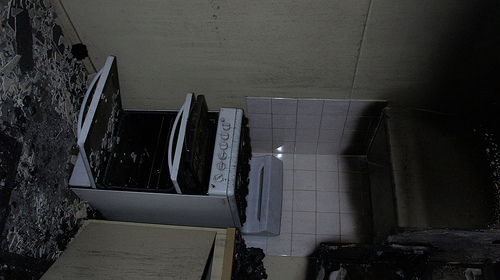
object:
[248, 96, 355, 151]
tile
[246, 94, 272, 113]
wall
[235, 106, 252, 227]
top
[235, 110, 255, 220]
eyes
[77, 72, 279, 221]
oven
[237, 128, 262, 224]
black burners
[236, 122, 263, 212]
burners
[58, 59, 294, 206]
stove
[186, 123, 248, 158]
knob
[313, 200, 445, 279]
cabinet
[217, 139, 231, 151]
white knob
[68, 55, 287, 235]
white stove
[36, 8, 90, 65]
tiles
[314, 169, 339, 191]
tile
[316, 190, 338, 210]
tile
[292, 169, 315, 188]
tile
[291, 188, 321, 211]
tile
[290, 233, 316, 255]
tile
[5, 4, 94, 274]
floor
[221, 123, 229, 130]
dial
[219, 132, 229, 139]
dial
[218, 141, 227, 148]
dial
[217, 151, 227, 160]
dial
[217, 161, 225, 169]
dial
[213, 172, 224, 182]
dial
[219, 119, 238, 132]
knob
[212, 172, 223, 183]
knob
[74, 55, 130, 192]
door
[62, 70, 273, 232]
oven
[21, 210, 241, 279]
cabinet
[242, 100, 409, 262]
wall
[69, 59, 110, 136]
handle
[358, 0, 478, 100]
wall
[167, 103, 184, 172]
handle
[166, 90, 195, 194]
door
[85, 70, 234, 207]
stove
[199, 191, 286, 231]
doors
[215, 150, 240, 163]
knob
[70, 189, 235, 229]
side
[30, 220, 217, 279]
door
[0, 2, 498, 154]
wall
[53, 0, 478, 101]
grime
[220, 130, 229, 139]
knob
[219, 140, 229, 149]
knob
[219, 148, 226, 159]
knob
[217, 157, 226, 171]
knob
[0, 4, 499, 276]
kitchen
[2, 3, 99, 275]
tile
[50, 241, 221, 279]
streaks